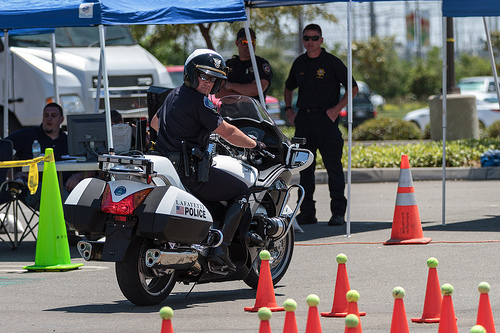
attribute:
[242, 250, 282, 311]
cone — orange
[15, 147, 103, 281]
cone — bright, yellow-green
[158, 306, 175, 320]
ball — tennis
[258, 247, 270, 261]
ball — tennis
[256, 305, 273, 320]
ball — tennis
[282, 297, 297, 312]
ball — tennis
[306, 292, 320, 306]
ball — tennis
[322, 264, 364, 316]
cone — orange, small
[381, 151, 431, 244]
cone — medium, orange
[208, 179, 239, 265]
boots — black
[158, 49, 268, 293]
officer — police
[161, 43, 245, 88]
helmet — white, black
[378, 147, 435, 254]
cone — large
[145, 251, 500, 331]
cones — orange, small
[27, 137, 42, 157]
bottle — small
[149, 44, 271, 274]
officer — police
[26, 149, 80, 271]
cone — green, bright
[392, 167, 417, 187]
tape — reflective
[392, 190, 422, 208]
tape — reflective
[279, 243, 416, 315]
cone — small, orange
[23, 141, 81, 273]
cone — large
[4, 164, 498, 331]
parking lot — paved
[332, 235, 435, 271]
asphalt — black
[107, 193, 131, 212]
light — tail, motorcycle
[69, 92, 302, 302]
motorcycle — police